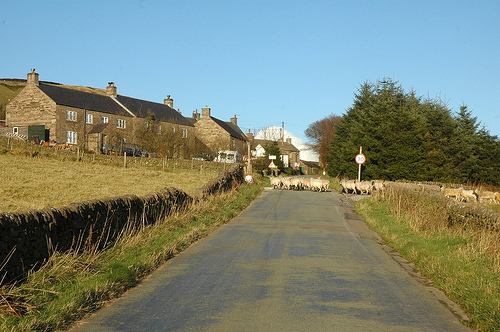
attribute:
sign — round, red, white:
[353, 149, 368, 165]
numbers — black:
[356, 156, 367, 161]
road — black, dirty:
[116, 183, 466, 329]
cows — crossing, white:
[267, 171, 389, 207]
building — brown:
[94, 75, 123, 96]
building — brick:
[24, 67, 46, 86]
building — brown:
[160, 90, 178, 108]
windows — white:
[64, 111, 80, 126]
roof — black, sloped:
[36, 80, 133, 117]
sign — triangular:
[264, 160, 279, 171]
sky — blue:
[138, 8, 369, 81]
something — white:
[256, 123, 298, 144]